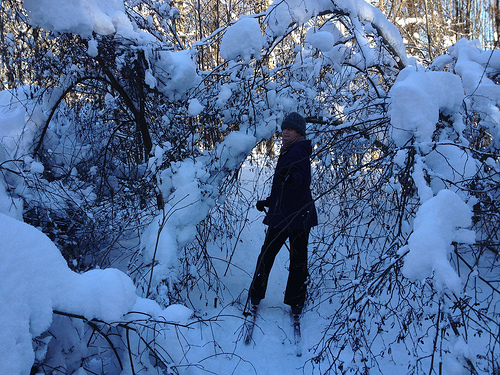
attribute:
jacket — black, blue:
[261, 147, 318, 229]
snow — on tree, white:
[4, 229, 193, 325]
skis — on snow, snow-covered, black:
[243, 292, 302, 356]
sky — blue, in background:
[396, 2, 496, 43]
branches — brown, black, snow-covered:
[11, 48, 157, 173]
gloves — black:
[257, 171, 295, 215]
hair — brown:
[285, 122, 305, 140]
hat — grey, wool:
[280, 113, 308, 135]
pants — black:
[246, 225, 306, 303]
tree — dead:
[1, 2, 191, 187]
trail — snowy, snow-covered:
[226, 158, 322, 373]